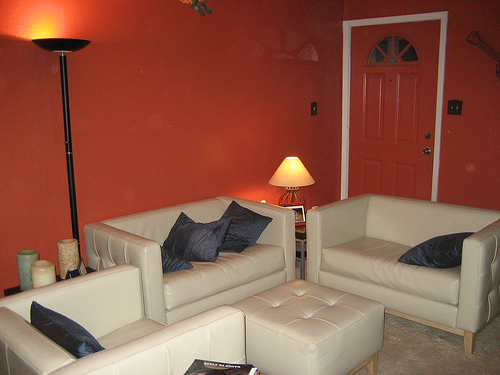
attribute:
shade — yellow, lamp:
[264, 154, 318, 194]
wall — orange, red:
[5, 5, 336, 311]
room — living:
[9, 3, 497, 373]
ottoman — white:
[225, 273, 382, 373]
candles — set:
[18, 235, 88, 300]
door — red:
[348, 21, 435, 201]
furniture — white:
[10, 192, 499, 372]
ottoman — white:
[221, 266, 383, 371]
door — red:
[353, 13, 449, 221]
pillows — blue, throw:
[147, 191, 284, 278]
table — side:
[3, 265, 93, 301]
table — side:
[292, 207, 316, 273]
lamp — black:
[31, 29, 102, 277]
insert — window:
[358, 31, 423, 67]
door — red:
[345, 15, 435, 215]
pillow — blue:
[404, 232, 470, 281]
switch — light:
[444, 95, 468, 115]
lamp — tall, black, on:
[33, 28, 93, 271]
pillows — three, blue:
[152, 199, 269, 275]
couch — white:
[77, 192, 295, 329]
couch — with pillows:
[82, 190, 298, 320]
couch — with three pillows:
[130, 191, 290, 301]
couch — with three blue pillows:
[78, 195, 290, 282]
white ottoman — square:
[227, 276, 386, 373]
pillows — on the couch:
[143, 202, 273, 272]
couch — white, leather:
[82, 194, 298, 310]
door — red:
[314, 6, 463, 255]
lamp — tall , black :
[24, 26, 129, 91]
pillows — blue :
[131, 180, 301, 289]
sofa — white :
[64, 177, 301, 289]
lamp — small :
[264, 146, 324, 198]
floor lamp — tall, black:
[33, 36, 91, 236]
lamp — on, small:
[266, 155, 316, 207]